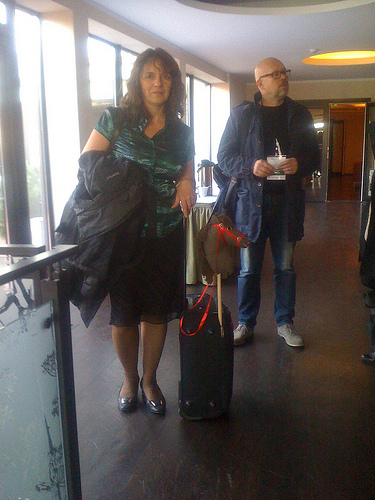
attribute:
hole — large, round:
[301, 49, 373, 65]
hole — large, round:
[178, 0, 372, 16]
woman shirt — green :
[78, 42, 177, 421]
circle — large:
[305, 50, 369, 66]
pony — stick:
[172, 211, 241, 352]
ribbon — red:
[178, 283, 217, 334]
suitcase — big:
[179, 251, 235, 389]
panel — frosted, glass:
[20, 76, 50, 267]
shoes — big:
[92, 356, 205, 439]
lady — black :
[82, 46, 196, 414]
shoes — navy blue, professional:
[118, 378, 166, 416]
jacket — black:
[49, 151, 152, 312]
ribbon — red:
[179, 280, 213, 334]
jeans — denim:
[238, 192, 299, 331]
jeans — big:
[237, 195, 293, 324]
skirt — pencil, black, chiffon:
[99, 218, 219, 343]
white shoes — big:
[226, 319, 304, 347]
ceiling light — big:
[295, 47, 374, 70]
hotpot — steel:
[193, 159, 216, 197]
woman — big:
[74, 37, 202, 422]